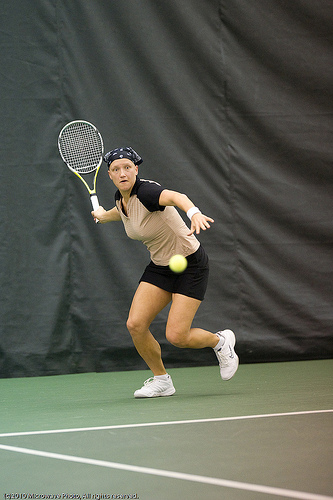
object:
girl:
[91, 147, 239, 397]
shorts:
[139, 245, 209, 301]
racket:
[57, 119, 105, 224]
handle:
[90, 195, 100, 224]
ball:
[169, 254, 188, 273]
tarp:
[0, 0, 333, 377]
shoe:
[214, 329, 239, 381]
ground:
[0, 355, 333, 500]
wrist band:
[187, 207, 201, 220]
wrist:
[186, 206, 201, 220]